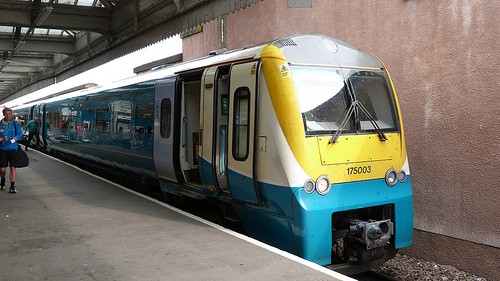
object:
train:
[0, 33, 417, 277]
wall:
[178, 0, 500, 281]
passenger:
[0, 107, 30, 193]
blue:
[9, 126, 16, 133]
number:
[347, 166, 371, 175]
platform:
[0, 142, 357, 280]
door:
[152, 62, 238, 196]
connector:
[331, 203, 401, 264]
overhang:
[0, 0, 215, 101]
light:
[319, 80, 337, 99]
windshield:
[286, 64, 401, 137]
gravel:
[403, 257, 443, 279]